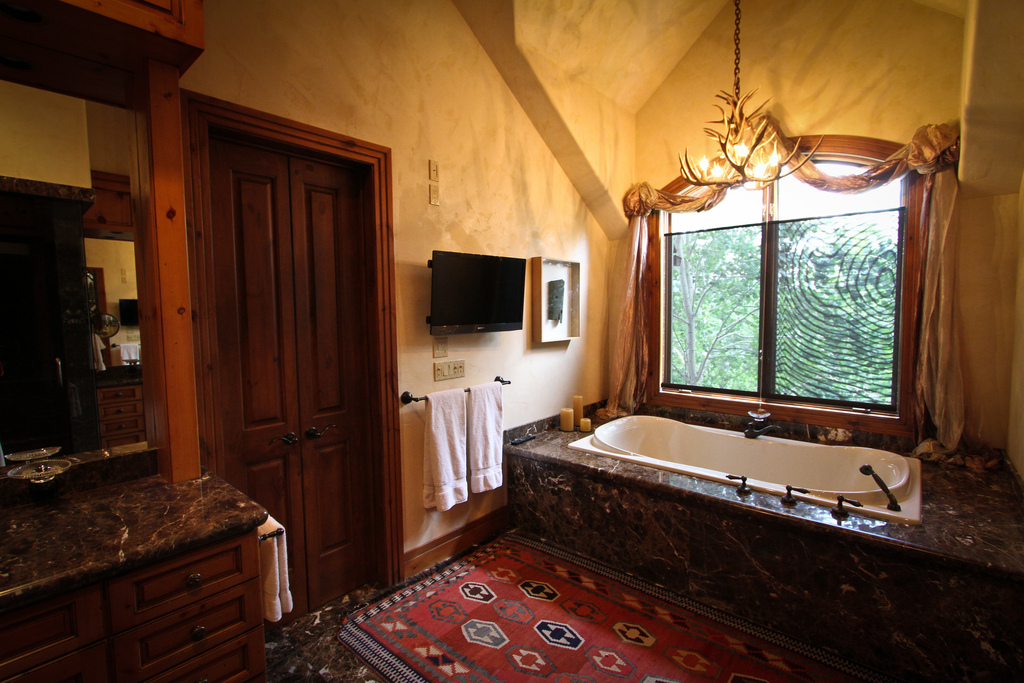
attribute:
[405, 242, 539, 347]
television — dark-screened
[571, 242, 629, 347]
artwork — textured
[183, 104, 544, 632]
door — wide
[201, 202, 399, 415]
panels — wooden, carved, rectangular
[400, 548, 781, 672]
rug — red and black, patterned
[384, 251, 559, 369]
television — flat screen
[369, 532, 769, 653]
rug — multi-colored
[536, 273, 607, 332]
shadow box — shadowy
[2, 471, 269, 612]
bathroom top — granite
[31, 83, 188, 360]
mirror — large